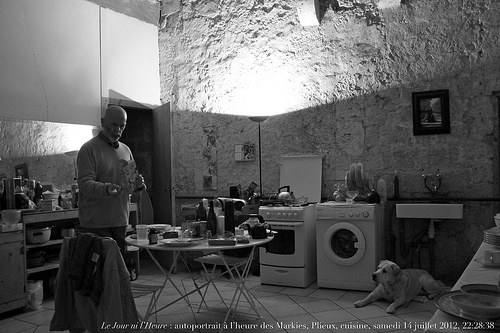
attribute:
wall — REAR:
[256, 77, 316, 124]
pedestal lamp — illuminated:
[250, 120, 263, 203]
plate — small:
[440, 272, 499, 318]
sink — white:
[397, 184, 474, 232]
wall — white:
[3, 3, 170, 197]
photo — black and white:
[10, 10, 491, 331]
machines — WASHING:
[257, 191, 402, 302]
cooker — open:
[188, 107, 325, 293]